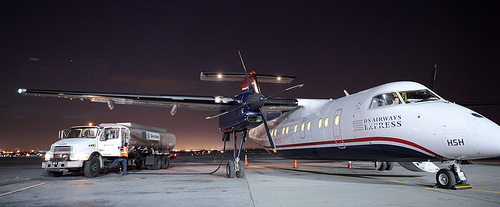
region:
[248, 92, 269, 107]
The core of the propeller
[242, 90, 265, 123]
The left jet engine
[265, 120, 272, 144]
A propeller blade facing down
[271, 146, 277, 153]
The yellow tip of a blade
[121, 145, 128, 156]
An orange reflective jacket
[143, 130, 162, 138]
A sign pasted on the fuel tanker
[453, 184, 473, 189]
A stopper in front of the wheel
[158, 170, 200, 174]
A fuel line on the ground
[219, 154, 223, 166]
A fuel line hanging down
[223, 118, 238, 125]
The plane's fuel tank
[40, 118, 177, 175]
white truck to the left of airplane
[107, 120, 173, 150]
silver tank on truck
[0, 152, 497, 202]
truck stopped on tarmac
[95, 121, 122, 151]
truck door is open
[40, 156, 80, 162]
truck bumper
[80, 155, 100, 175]
large black tire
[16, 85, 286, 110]
airplane wing over truck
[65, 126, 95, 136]
windshield on truck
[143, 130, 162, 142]
white sign on tank of truck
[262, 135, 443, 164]
red stripe on airplane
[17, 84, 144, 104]
A wing of a plane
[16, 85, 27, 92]
The white tip of a wing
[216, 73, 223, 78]
A bright shining light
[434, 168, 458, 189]
The front wheel of a plane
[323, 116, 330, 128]
Light shining through a window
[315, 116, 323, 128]
The planes round window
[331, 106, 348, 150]
A window in the plane door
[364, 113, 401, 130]
The airline's name on the side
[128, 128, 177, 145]
A metallic fuel tank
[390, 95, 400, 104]
A pilot in the cockpit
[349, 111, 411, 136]
U.S. Airways Express logo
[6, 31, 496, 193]
a small airplain at the airport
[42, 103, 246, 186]
a truck refueling an airplane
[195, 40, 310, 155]
the propeller of an airplane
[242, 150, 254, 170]
an orange cone on the runway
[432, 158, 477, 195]
front landing gear of an airplane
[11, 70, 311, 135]
wing of an airplane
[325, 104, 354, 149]
a closed door to the cabin of an airplane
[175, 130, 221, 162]
lights of a city at night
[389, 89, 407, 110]
a pilot in the cockpit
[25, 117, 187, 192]
a tanker truck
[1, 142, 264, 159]
a city in the background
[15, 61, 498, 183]
a large airplane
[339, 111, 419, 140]
a US Airways Express logo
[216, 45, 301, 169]
an airplane's right propeller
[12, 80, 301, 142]
an airplane's right wing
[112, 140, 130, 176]
a person standing by a truck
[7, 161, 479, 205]
a flat asphalt surface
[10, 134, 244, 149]
a glow on the horizon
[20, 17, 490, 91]
a dark night sky